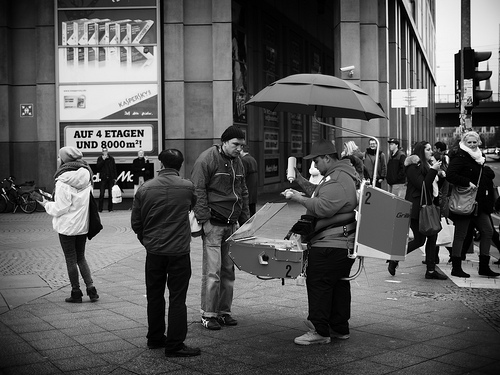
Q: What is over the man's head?
A: Umbrella.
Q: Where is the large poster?
A: On the building.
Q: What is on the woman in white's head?
A: Wool hat.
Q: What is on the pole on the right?
A: Traffic signal.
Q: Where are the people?
A: Sidewalk.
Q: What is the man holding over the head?
A: Umbrella.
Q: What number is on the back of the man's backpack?
A: 2.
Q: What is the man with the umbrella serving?
A: Hot dogs.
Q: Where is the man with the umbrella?
A: Sidewalk.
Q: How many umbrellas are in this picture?
A: One.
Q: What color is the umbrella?
A: Black.